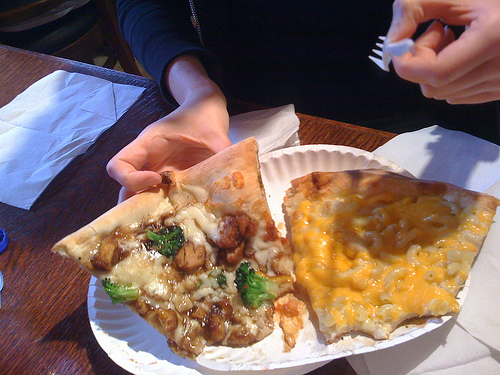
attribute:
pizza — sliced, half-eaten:
[50, 135, 309, 360]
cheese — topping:
[303, 217, 430, 312]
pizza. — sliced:
[283, 160, 495, 339]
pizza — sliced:
[283, 167, 465, 300]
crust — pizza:
[197, 140, 277, 200]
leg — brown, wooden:
[91, 12, 146, 87]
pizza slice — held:
[47, 138, 306, 352]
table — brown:
[5, 44, 399, 372]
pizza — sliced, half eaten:
[48, 139, 299, 350]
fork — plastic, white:
[351, 31, 431, 74]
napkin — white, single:
[0, 69, 145, 209]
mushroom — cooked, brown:
[169, 239, 211, 276]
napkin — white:
[6, 75, 119, 208]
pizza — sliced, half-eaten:
[282, 170, 498, 344]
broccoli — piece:
[234, 258, 274, 305]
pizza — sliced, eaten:
[289, 160, 488, 340]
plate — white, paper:
[85, 142, 470, 374]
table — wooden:
[8, 41, 496, 373]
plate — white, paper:
[61, 152, 468, 369]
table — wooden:
[14, 216, 124, 336]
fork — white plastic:
[365, 40, 435, 85]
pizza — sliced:
[162, 160, 444, 340]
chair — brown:
[0, 1, 145, 77]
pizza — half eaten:
[296, 181, 451, 301]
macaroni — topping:
[351, 240, 417, 287]